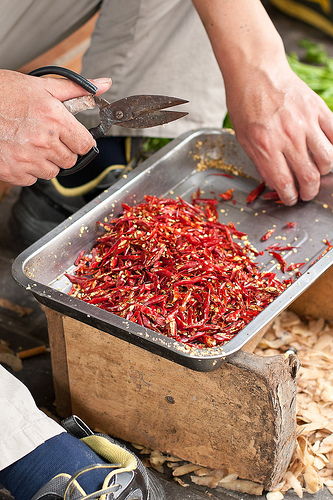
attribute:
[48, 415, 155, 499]
shoe — black, silver, untied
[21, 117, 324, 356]
tin — messy, silver, full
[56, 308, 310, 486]
block — wood, natural, turned over, wooden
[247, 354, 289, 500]
wood — natural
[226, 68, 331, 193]
hand — reaching, scooping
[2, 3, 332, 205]
man — working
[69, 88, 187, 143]
shears — rusty, rusted, old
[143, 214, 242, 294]
peppers — red, cut, chili, tiny, small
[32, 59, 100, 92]
handle — black, covered, plastic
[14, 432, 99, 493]
sock — blue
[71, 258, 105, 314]
chilis — red, tiny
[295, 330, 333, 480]
shavings — wood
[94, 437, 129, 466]
interior — yellow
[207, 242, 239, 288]
chilies — red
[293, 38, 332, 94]
leaves — dried, blurred, green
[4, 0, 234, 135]
pants — tan, light